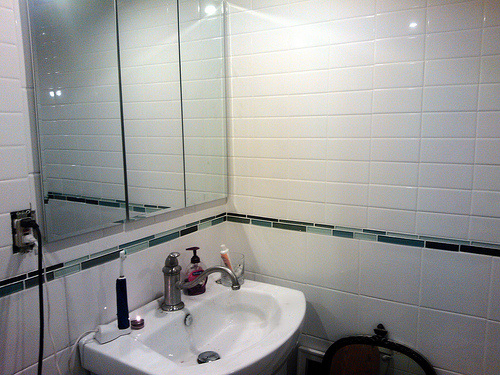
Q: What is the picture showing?
A: It is showing a bathroom.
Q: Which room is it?
A: It is a bathroom.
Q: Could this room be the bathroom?
A: Yes, it is the bathroom.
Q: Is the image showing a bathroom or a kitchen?
A: It is showing a bathroom.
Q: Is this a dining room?
A: No, it is a bathroom.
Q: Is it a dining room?
A: No, it is a bathroom.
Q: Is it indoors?
A: Yes, it is indoors.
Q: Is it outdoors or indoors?
A: It is indoors.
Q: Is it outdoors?
A: No, it is indoors.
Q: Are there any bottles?
A: Yes, there is a bottle.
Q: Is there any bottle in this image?
A: Yes, there is a bottle.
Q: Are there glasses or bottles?
A: Yes, there is a bottle.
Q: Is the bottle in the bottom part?
A: Yes, the bottle is in the bottom of the image.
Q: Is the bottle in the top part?
A: No, the bottle is in the bottom of the image.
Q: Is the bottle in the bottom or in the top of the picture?
A: The bottle is in the bottom of the image.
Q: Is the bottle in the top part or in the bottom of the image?
A: The bottle is in the bottom of the image.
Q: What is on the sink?
A: The bottle is on the sink.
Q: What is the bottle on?
A: The bottle is on the sink.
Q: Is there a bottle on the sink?
A: Yes, there is a bottle on the sink.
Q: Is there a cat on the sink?
A: No, there is a bottle on the sink.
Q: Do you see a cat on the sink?
A: No, there is a bottle on the sink.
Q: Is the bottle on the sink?
A: Yes, the bottle is on the sink.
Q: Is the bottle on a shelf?
A: No, the bottle is on the sink.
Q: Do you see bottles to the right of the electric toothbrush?
A: Yes, there is a bottle to the right of the electric toothbrush.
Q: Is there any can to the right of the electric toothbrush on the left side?
A: No, there is a bottle to the right of the electric toothbrush.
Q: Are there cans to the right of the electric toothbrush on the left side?
A: No, there is a bottle to the right of the electric toothbrush.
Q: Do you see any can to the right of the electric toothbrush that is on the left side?
A: No, there is a bottle to the right of the electric toothbrush.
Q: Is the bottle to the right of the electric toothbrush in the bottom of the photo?
A: Yes, the bottle is to the right of the electric toothbrush.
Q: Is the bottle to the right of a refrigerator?
A: No, the bottle is to the right of the electric toothbrush.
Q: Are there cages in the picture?
A: No, there are no cages.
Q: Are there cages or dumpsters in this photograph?
A: No, there are no cages or dumpsters.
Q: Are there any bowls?
A: No, there are no bowls.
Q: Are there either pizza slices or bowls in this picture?
A: No, there are no bowls or pizza slices.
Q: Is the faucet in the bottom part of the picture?
A: Yes, the faucet is in the bottom of the image.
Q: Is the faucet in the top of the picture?
A: No, the faucet is in the bottom of the image.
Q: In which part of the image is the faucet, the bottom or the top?
A: The faucet is in the bottom of the image.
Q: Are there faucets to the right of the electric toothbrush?
A: Yes, there is a faucet to the right of the electric toothbrush.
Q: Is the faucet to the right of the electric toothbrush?
A: Yes, the faucet is to the right of the electric toothbrush.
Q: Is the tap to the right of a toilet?
A: No, the tap is to the right of the electric toothbrush.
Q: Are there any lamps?
A: No, there are no lamps.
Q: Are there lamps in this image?
A: No, there are no lamps.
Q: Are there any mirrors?
A: Yes, there is a mirror.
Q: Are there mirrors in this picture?
A: Yes, there is a mirror.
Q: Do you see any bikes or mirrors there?
A: Yes, there is a mirror.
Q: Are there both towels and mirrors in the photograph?
A: No, there is a mirror but no towels.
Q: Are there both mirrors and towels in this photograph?
A: No, there is a mirror but no towels.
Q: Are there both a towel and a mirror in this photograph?
A: No, there is a mirror but no towels.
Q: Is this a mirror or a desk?
A: This is a mirror.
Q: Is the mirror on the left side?
A: Yes, the mirror is on the left of the image.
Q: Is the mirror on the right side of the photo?
A: No, the mirror is on the left of the image.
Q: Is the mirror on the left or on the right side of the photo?
A: The mirror is on the left of the image.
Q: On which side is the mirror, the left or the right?
A: The mirror is on the left of the image.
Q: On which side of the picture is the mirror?
A: The mirror is on the left of the image.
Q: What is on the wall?
A: The mirror is on the wall.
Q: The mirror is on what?
A: The mirror is on the wall.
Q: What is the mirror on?
A: The mirror is on the wall.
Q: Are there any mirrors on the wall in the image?
A: Yes, there is a mirror on the wall.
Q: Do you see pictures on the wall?
A: No, there is a mirror on the wall.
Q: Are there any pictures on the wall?
A: No, there is a mirror on the wall.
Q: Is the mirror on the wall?
A: Yes, the mirror is on the wall.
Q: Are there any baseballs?
A: No, there are no baseballs.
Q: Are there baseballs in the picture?
A: No, there are no baseballs.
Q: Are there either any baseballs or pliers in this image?
A: No, there are no baseballs or pliers.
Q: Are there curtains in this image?
A: No, there are no curtains.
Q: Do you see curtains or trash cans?
A: No, there are no curtains or trash cans.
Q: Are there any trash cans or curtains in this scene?
A: No, there are no curtains or trash cans.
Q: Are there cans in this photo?
A: No, there are no cans.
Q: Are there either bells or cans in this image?
A: No, there are no cans or bells.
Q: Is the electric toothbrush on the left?
A: Yes, the electric toothbrush is on the left of the image.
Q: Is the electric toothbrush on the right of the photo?
A: No, the electric toothbrush is on the left of the image.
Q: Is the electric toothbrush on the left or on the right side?
A: The electric toothbrush is on the left of the image.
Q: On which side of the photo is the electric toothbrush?
A: The electric toothbrush is on the left of the image.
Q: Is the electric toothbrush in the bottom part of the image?
A: Yes, the electric toothbrush is in the bottom of the image.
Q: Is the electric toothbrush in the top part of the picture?
A: No, the electric toothbrush is in the bottom of the image.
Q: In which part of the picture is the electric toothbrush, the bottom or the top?
A: The electric toothbrush is in the bottom of the image.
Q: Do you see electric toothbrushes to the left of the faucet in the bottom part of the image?
A: Yes, there is an electric toothbrush to the left of the faucet.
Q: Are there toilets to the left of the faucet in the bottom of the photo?
A: No, there is an electric toothbrush to the left of the faucet.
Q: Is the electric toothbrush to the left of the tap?
A: Yes, the electric toothbrush is to the left of the tap.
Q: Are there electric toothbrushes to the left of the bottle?
A: Yes, there is an electric toothbrush to the left of the bottle.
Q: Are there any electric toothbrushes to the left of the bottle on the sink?
A: Yes, there is an electric toothbrush to the left of the bottle.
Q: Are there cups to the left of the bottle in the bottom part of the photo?
A: No, there is an electric toothbrush to the left of the bottle.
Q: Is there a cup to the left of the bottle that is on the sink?
A: No, there is an electric toothbrush to the left of the bottle.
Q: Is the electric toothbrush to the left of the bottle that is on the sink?
A: Yes, the electric toothbrush is to the left of the bottle.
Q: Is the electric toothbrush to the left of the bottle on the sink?
A: Yes, the electric toothbrush is to the left of the bottle.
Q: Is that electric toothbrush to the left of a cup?
A: No, the electric toothbrush is to the left of the bottle.